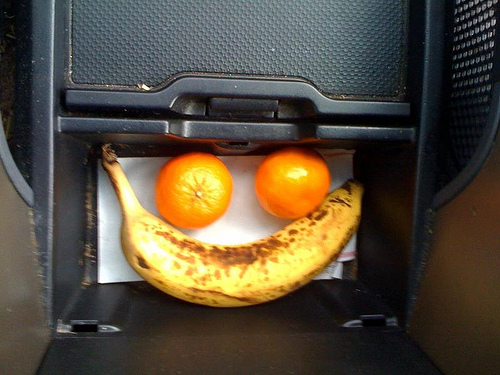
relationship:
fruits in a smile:
[99, 141, 372, 307] [94, 139, 361, 304]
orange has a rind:
[152, 154, 229, 229] [160, 151, 231, 226]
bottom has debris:
[38, 131, 428, 328] [80, 171, 109, 294]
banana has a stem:
[102, 151, 366, 317] [95, 143, 136, 209]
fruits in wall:
[99, 141, 372, 307] [2, 183, 499, 353]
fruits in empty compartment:
[99, 141, 372, 307] [46, 10, 416, 135]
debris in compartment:
[80, 171, 109, 294] [46, 10, 416, 135]